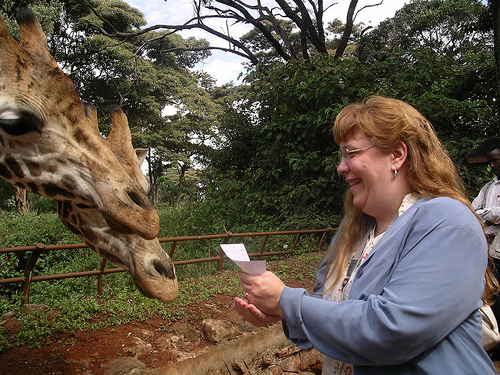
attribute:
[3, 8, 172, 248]
heads — long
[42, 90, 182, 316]
heads — long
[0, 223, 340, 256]
pole — long, brown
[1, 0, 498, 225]
trees — bare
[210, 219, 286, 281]
paper — white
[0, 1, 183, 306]
giraffe — brown, white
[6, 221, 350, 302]
fence — brown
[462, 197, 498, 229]
arms — crossed